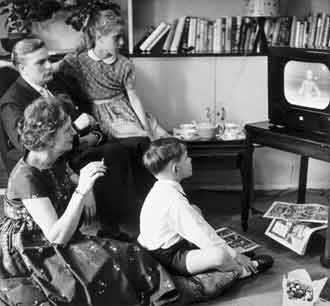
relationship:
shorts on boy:
[150, 232, 200, 274] [132, 138, 267, 278]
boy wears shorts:
[132, 138, 267, 278] [150, 232, 200, 274]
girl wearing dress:
[5, 5, 171, 216] [71, 55, 159, 149]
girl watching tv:
[5, 5, 171, 216] [263, 46, 329, 135]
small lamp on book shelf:
[243, 1, 280, 50] [123, 0, 327, 54]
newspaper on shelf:
[261, 193, 319, 249] [240, 120, 330, 233]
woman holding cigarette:
[0, 93, 176, 302] [100, 157, 104, 161]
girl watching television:
[69, 5, 170, 138] [267, 46, 330, 135]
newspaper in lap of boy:
[211, 224, 257, 251] [132, 138, 267, 278]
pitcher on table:
[191, 112, 223, 144] [71, 133, 259, 234]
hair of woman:
[16, 99, 80, 155] [4, 94, 150, 304]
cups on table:
[167, 115, 245, 141] [199, 144, 250, 156]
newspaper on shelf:
[261, 193, 319, 249] [245, 130, 306, 203]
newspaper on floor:
[215, 226, 262, 254] [102, 143, 324, 302]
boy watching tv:
[132, 138, 267, 278] [267, 44, 328, 137]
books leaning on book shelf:
[138, 8, 330, 55] [1, 0, 330, 61]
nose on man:
[46, 63, 51, 71] [0, 36, 136, 244]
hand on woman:
[75, 156, 111, 187] [9, 95, 148, 288]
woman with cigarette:
[0, 93, 176, 302] [100, 155, 106, 163]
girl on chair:
[5, 5, 171, 216] [3, 64, 143, 208]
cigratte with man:
[85, 113, 100, 129] [5, 31, 102, 181]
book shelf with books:
[1, 0, 329, 62] [181, 17, 267, 51]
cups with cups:
[173, 120, 247, 141] [173, 120, 247, 141]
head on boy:
[139, 136, 194, 182] [132, 138, 267, 278]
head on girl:
[86, 9, 126, 57] [52, 6, 165, 143]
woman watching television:
[0, 96, 274, 306] [265, 64, 329, 159]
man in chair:
[8, 39, 132, 244] [1, 64, 150, 225]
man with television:
[8, 39, 132, 244] [266, 41, 328, 141]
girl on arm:
[5, 5, 171, 216] [105, 134, 153, 155]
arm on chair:
[105, 134, 153, 155] [0, 53, 130, 237]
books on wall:
[133, 17, 329, 50] [173, 0, 213, 16]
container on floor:
[282, 271, 325, 304] [250, 283, 272, 299]